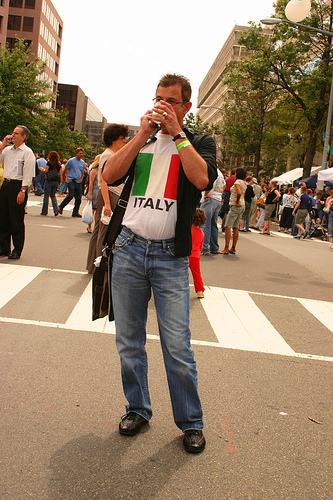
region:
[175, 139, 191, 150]
a fluorescent green wrist band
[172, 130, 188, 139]
a wrist watch on the mans wrist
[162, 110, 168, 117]
a ring on the mans finger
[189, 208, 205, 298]
a child in a red shirt and pants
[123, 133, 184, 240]
a man wearing an Italy t-shirt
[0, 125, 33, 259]
a man talking on a cell phone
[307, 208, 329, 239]
a baby in a stroller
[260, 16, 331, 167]
a street light above the crowd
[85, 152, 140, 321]
the mans brown leather shoulder bag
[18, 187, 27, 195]
a wrist watch on his left wrist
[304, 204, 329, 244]
A child is sitting in a stroller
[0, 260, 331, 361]
White lines are painted on the street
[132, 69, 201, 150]
Man wearing a neon green armband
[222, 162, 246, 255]
A woman standing in the street with her hand on her hip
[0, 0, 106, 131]
Group of tall buildings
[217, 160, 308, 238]
People gathered in the street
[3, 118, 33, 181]
A man talking on his cell phone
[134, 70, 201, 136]
A man drinking from a cup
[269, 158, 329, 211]
Tents are set up on one side of the street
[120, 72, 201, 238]
A man is wearing a white shirt with Italy's flag on the front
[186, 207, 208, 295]
small child behind man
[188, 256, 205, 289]
child is wearing red pants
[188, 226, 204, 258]
child is wearing a red shirt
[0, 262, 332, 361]
crosswalk under child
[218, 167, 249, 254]
person standing on the street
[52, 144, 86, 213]
man wearing a blue t shirt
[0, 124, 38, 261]
man talking on his cellphone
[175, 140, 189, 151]
bright green wrist band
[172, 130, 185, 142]
wrist watch above wrist band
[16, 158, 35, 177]
man carrying a newspaper under his arm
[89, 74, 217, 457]
man standing on the street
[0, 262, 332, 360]
pedestrian lines on the street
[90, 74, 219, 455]
young man carrying bag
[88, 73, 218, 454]
man wearing blue jeans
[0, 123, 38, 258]
man wearing black pants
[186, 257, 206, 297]
right leg showing behind man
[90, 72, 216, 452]
man wearing glasses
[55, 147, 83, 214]
man walking on the street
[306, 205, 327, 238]
baby carriage on the corner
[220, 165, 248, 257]
woman standing on the street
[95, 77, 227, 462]
man in center a street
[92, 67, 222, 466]
man holds a glass with both hands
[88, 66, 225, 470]
man is drinking from a glass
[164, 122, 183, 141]
a clock on a wrist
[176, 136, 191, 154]
a green bracelet on arm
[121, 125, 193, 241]
a white tee shirt with the Italian flag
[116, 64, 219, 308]
a toddler behind a man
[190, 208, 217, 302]
toddler wears red cloths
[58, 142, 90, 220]
a man with blue shirt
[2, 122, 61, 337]
man stands in front crossing lines